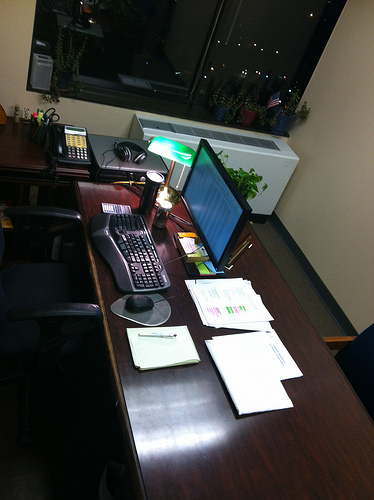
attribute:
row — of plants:
[208, 72, 311, 135]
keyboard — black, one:
[90, 212, 170, 291]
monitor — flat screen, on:
[179, 138, 253, 271]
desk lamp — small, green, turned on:
[147, 136, 196, 211]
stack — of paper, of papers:
[184, 277, 274, 333]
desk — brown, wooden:
[75, 180, 373, 500]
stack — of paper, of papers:
[203, 330, 304, 417]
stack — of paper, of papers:
[125, 325, 201, 372]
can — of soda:
[152, 199, 174, 230]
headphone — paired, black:
[115, 140, 149, 164]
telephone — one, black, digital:
[46, 122, 93, 193]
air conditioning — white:
[127, 111, 300, 224]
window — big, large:
[26, 0, 347, 139]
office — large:
[1, 1, 374, 500]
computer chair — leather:
[1, 204, 103, 408]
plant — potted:
[40, 23, 89, 104]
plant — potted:
[204, 76, 245, 125]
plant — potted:
[235, 94, 269, 131]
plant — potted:
[266, 88, 311, 135]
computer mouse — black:
[125, 294, 154, 315]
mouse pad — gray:
[109, 292, 173, 326]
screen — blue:
[183, 147, 244, 263]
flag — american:
[266, 89, 280, 109]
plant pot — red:
[236, 107, 258, 125]